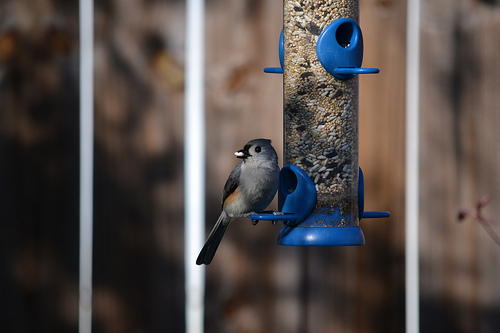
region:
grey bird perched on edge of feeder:
[193, 123, 287, 272]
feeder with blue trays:
[267, 2, 382, 260]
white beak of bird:
[226, 145, 248, 159]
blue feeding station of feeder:
[312, 15, 382, 82]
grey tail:
[192, 206, 236, 273]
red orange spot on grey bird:
[222, 184, 248, 214]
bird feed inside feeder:
[292, 72, 347, 160]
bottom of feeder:
[280, 227, 374, 252]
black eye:
[252, 143, 267, 160]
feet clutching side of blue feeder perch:
[235, 210, 274, 229]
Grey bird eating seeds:
[177, 123, 297, 283]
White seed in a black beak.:
[230, 144, 252, 161]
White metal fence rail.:
[169, 3, 225, 332]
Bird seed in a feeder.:
[293, 92, 349, 162]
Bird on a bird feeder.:
[151, 0, 390, 267]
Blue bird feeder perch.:
[317, 14, 382, 93]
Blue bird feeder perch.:
[347, 154, 390, 231]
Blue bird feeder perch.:
[261, 15, 296, 86]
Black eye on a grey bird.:
[255, 142, 264, 157]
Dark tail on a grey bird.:
[191, 205, 236, 275]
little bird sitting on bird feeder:
[188, 120, 337, 271]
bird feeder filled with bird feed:
[269, 0, 402, 275]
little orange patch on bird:
[211, 181, 256, 217]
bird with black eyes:
[236, 131, 289, 180]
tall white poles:
[399, 3, 431, 330]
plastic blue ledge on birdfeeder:
[317, 16, 388, 88]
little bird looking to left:
[183, 121, 290, 280]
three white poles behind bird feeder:
[75, 1, 462, 332]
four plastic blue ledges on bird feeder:
[225, 2, 407, 258]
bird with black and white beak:
[200, 129, 288, 169]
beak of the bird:
[232, 143, 246, 162]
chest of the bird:
[249, 164, 276, 204]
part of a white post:
[382, 86, 427, 245]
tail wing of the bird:
[203, 214, 227, 269]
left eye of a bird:
[248, 138, 265, 155]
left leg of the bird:
[274, 205, 286, 222]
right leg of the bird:
[247, 206, 264, 232]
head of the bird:
[245, 135, 266, 144]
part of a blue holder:
[319, 42, 374, 78]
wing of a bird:
[226, 175, 235, 193]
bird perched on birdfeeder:
[126, 105, 397, 270]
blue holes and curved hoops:
[231, 7, 381, 127]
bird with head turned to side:
[186, 115, 296, 275]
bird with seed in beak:
[185, 120, 295, 190]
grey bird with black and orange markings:
[180, 120, 295, 285]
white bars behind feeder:
[60, 71, 465, 286]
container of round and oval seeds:
[265, 10, 367, 255]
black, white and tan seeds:
[276, 66, 366, 163]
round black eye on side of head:
[246, 137, 263, 153]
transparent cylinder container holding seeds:
[271, 15, 391, 255]